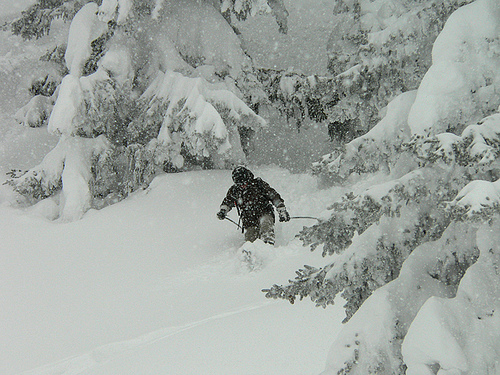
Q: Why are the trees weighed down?
A: From the snow.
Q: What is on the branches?
A: Snow.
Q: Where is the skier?
A: Between the trees.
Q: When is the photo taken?
A: Daytime.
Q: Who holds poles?
A: The skier.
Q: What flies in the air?
A: Pieces of snow.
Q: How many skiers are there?
A: One.